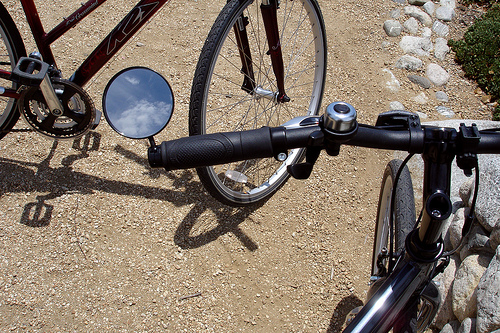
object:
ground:
[2, 0, 499, 332]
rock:
[380, 65, 403, 95]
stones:
[383, 0, 464, 122]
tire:
[186, 0, 332, 208]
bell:
[318, 101, 359, 136]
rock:
[383, 0, 459, 58]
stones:
[426, 154, 499, 332]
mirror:
[101, 67, 175, 142]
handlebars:
[146, 100, 500, 172]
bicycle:
[0, 0, 327, 209]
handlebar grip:
[147, 124, 288, 169]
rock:
[425, 63, 451, 88]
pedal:
[0, 51, 104, 146]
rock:
[388, 91, 452, 118]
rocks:
[410, 118, 499, 333]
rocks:
[378, 0, 467, 120]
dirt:
[0, 0, 499, 333]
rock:
[46, 254, 73, 278]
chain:
[9, 80, 98, 139]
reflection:
[102, 67, 172, 137]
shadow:
[0, 130, 259, 252]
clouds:
[104, 69, 173, 139]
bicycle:
[102, 66, 499, 333]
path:
[376, 0, 465, 121]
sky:
[105, 69, 175, 142]